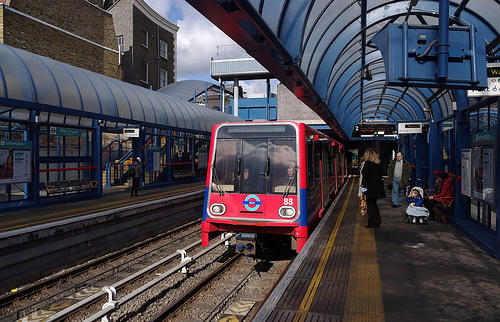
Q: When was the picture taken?
A: Daytime.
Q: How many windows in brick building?
A: 4.